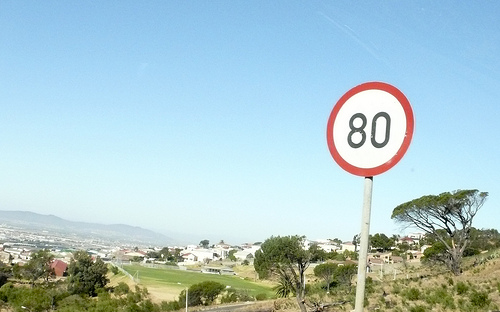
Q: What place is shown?
A: It is a field.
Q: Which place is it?
A: It is a field.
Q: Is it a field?
A: Yes, it is a field.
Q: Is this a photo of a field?
A: Yes, it is showing a field.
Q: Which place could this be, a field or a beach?
A: It is a field.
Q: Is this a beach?
A: No, it is a field.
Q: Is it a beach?
A: No, it is a field.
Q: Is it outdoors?
A: Yes, it is outdoors.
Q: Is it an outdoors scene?
A: Yes, it is outdoors.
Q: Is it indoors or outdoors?
A: It is outdoors.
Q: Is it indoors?
A: No, it is outdoors.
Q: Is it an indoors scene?
A: No, it is outdoors.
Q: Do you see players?
A: No, there are no players.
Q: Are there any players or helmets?
A: No, there are no players or helmets.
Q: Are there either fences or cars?
A: No, there are no cars or fences.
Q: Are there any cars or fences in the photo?
A: No, there are no cars or fences.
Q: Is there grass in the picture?
A: Yes, there is grass.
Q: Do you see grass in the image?
A: Yes, there is grass.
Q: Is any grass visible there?
A: Yes, there is grass.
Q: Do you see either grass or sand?
A: Yes, there is grass.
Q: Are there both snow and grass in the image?
A: No, there is grass but no snow.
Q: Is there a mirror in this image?
A: No, there are no mirrors.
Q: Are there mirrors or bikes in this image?
A: No, there are no mirrors or bikes.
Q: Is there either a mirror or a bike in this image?
A: No, there are no mirrors or bikes.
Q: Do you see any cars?
A: No, there are no cars.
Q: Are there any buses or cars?
A: No, there are no cars or buses.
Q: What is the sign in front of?
A: The sign is in front of the tree.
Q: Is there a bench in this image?
A: No, there are no benches.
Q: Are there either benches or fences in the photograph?
A: No, there are no benches or fences.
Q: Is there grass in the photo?
A: Yes, there is grass.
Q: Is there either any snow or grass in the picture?
A: Yes, there is grass.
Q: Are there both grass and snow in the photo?
A: No, there is grass but no snow.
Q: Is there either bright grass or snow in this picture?
A: Yes, there is bright grass.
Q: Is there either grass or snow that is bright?
A: Yes, the grass is bright.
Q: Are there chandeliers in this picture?
A: No, there are no chandeliers.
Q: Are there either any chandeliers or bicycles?
A: No, there are no chandeliers or bicycles.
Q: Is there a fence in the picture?
A: No, there are no fences.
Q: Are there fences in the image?
A: No, there are no fences.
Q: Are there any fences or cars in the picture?
A: No, there are no fences or cars.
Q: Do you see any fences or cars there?
A: No, there are no fences or cars.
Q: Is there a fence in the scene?
A: No, there are no fences.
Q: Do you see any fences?
A: No, there are no fences.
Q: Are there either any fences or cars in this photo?
A: No, there are no fences or cars.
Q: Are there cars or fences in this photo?
A: No, there are no fences or cars.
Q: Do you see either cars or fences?
A: No, there are no fences or cars.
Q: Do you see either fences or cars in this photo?
A: No, there are no fences or cars.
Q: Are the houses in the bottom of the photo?
A: Yes, the houses are in the bottom of the image.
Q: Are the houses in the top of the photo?
A: No, the houses are in the bottom of the image.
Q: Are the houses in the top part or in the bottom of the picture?
A: The houses are in the bottom of the image.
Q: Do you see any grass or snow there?
A: Yes, there is grass.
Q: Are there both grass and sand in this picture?
A: No, there is grass but no sand.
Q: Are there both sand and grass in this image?
A: No, there is grass but no sand.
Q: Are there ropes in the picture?
A: No, there are no ropes.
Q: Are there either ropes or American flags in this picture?
A: No, there are no ropes or American flags.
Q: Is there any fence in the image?
A: No, there are no fences.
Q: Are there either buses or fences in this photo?
A: No, there are no fences or buses.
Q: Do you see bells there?
A: No, there are no bells.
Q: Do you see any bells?
A: No, there are no bells.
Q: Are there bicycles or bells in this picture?
A: No, there are no bells or bicycles.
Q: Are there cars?
A: No, there are no cars.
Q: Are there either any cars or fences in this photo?
A: No, there are no cars or fences.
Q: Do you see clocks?
A: No, there are no clocks.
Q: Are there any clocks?
A: No, there are no clocks.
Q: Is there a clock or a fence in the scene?
A: No, there are no clocks or fences.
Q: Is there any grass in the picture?
A: Yes, there is grass.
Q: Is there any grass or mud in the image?
A: Yes, there is grass.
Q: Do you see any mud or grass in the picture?
A: Yes, there is grass.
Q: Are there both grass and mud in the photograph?
A: No, there is grass but no mud.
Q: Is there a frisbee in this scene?
A: No, there are no frisbees.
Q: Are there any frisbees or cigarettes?
A: No, there are no frisbees or cigarettes.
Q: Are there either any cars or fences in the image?
A: No, there are no cars or fences.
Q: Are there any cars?
A: No, there are no cars.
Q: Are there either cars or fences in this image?
A: No, there are no cars or fences.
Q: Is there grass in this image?
A: Yes, there is grass.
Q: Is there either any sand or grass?
A: Yes, there is grass.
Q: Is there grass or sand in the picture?
A: Yes, there is grass.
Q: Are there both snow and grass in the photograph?
A: No, there is grass but no snow.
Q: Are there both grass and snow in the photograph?
A: No, there is grass but no snow.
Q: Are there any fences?
A: No, there are no fences.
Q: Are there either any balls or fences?
A: No, there are no fences or balls.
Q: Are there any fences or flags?
A: No, there are no fences or flags.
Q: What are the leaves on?
A: The leaves are on the tree.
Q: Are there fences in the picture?
A: No, there are no fences.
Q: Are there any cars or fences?
A: No, there are no fences or cars.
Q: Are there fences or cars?
A: No, there are no fences or cars.